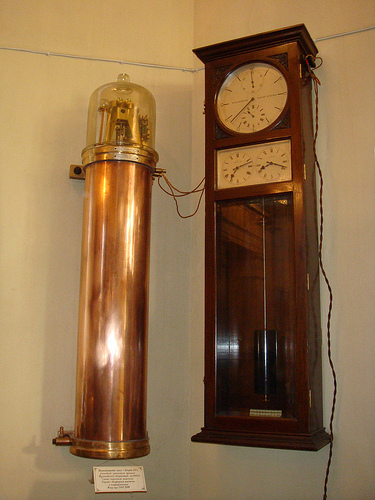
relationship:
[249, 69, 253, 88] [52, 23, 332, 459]
line on device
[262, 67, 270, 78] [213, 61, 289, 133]
line on device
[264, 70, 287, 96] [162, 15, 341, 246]
black line on device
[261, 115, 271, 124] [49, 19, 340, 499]
black line on device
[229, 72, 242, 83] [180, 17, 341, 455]
line on device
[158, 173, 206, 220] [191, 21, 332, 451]
wire connecting clock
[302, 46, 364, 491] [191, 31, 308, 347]
wire hang from clock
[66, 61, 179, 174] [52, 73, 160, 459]
glass on top of barometer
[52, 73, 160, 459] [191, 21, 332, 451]
barometer next to clock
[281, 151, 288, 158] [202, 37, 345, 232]
numeral on clock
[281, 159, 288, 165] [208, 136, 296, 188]
numeral on clock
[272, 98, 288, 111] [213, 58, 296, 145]
roman numeral on clock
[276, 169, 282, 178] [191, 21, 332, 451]
numeral on clock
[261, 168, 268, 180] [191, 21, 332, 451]
vii on clock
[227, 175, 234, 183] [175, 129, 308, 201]
numeral on clock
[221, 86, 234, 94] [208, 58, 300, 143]
numeral on clock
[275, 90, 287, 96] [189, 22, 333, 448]
line on device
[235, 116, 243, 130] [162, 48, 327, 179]
line on device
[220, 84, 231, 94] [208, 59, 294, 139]
line on device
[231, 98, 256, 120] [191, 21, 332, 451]
hand on clock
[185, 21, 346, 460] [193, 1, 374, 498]
clock on wall